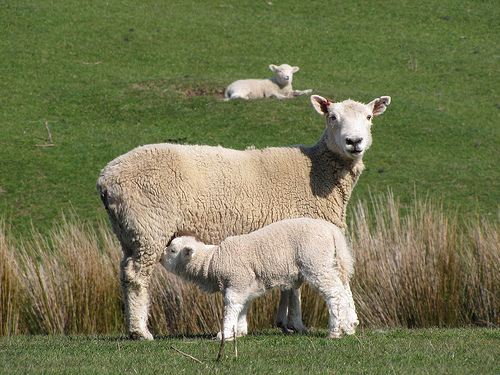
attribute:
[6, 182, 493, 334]
grass — BROWN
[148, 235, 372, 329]
lamb — SMALL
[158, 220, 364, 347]
lamb — little, fluffy, fuzzy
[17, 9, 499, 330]
grass — green, lush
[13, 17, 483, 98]
field — grass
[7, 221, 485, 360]
field — grass